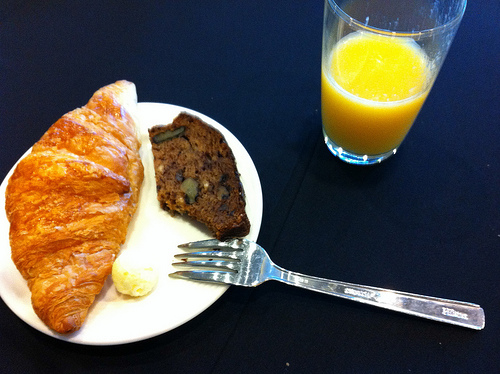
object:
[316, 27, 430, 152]
juice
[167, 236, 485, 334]
fork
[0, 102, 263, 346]
plate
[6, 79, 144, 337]
bread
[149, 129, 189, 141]
pepper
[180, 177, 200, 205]
onion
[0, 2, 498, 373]
tablecloth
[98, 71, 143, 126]
croissant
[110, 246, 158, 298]
butter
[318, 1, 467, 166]
cup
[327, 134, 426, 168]
glass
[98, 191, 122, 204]
nuts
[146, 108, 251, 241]
food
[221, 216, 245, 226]
fruit cake